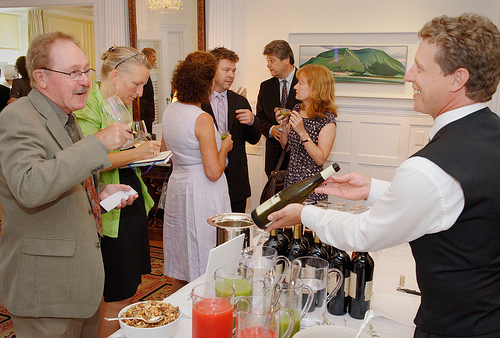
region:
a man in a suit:
[1, 30, 118, 337]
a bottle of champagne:
[251, 158, 339, 235]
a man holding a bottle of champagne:
[253, 13, 498, 335]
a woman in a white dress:
[166, 50, 232, 279]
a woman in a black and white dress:
[288, 67, 335, 177]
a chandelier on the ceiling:
[146, 0, 186, 15]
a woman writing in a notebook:
[99, 45, 174, 174]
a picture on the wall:
[297, 34, 415, 95]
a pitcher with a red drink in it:
[188, 285, 244, 337]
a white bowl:
[117, 298, 182, 337]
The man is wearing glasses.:
[45, 62, 109, 79]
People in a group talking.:
[170, 50, 345, 193]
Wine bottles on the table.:
[303, 234, 378, 306]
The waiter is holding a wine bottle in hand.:
[243, 160, 345, 232]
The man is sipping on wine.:
[81, 85, 159, 163]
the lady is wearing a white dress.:
[165, 50, 242, 246]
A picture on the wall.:
[275, 27, 410, 110]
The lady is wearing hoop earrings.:
[100, 81, 122, 105]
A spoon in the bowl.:
[91, 300, 171, 330]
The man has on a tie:
[265, 76, 301, 116]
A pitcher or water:
[288, 251, 336, 323]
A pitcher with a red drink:
[180, 275, 235, 335]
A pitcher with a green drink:
[202, 255, 262, 330]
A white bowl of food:
[101, 290, 181, 335]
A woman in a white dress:
[155, 50, 240, 295]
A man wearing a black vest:
[242, 7, 497, 332]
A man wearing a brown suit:
[0, 25, 140, 335]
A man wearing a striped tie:
[250, 40, 305, 195]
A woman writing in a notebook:
[70, 37, 170, 332]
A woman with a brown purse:
[261, 65, 332, 206]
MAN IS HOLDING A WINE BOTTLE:
[273, 198, 303, 231]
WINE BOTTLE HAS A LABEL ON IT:
[263, 198, 268, 208]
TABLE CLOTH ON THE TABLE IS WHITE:
[393, 301, 410, 316]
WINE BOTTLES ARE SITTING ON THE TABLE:
[328, 266, 375, 319]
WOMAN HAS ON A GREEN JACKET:
[89, 113, 104, 120]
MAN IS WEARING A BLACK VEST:
[458, 148, 471, 171]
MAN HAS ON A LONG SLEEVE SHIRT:
[399, 193, 425, 224]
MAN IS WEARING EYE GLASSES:
[65, 71, 95, 81]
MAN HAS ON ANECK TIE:
[82, 180, 100, 205]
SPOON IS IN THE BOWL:
[148, 312, 155, 322]